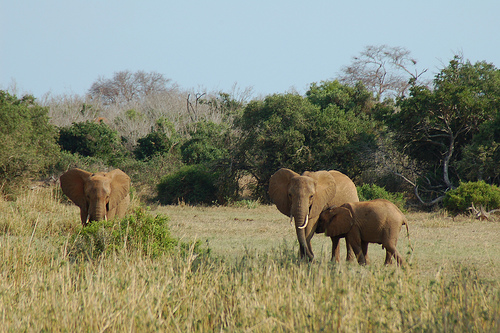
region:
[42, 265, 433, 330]
the field is brown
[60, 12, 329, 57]
the sky is dreary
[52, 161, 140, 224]
the elephant is standing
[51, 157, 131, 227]
the elephant is forward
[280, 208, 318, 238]
the elephant has tusks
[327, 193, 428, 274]
the elephant is a baby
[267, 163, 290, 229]
the elephant has a big ear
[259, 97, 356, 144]
the trees are healthy and lush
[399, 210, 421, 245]
the elephant has a small tail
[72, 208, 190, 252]
the bush is small and green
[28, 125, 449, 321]
elephants standing on flat ground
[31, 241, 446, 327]
tan grasses with spots of green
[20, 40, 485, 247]
trees of varying heights behind elephants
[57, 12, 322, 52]
clear light blue sky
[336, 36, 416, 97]
leafless tree above other trees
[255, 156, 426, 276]
adult with side to young elephant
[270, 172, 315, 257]
tusk curled in front of trunk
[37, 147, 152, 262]
elephant behind green shrub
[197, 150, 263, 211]
opening between tree and shrub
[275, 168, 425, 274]
young elephant reaching under adult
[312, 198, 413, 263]
a baby elephant nursing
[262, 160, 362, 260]
a mother elephant with her baby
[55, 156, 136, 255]
an elephant standing near a mother elephant and her baby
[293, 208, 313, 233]
a white ivory tusk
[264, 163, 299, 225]
a large elephant ear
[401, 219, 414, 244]
a baby elephant tail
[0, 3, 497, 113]
a pale blue sky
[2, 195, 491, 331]
dry savannah grass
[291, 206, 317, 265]
a long elephant trunk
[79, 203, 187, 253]
a bush in front of an elephant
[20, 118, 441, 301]
elephants outside in nature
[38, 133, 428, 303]
some elephants outside in nature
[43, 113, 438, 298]
three elephants outside in nature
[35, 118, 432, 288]
big elephants outside in nature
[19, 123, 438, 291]
strong elephants outside in nature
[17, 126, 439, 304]
group of elephants outside in nature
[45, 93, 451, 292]
mighty elephants outside in nature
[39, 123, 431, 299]
nice size elephants outside in nature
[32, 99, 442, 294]
powerful elephants outside in nature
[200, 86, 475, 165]
set of green trees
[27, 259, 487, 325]
tall brown grass in front of elephants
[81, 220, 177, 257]
a clump of tall green grass in front of an elephant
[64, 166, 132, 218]
a brown elephant standing behind grass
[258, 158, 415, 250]
a mother and baby elephant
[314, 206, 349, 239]
a baby elephant's head underneath its mother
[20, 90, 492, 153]
several green trees behind the elephants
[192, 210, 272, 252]
open flat grass land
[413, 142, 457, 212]
an oddly curved tree to the right of the elephants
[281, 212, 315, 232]
two white tusks on an elephant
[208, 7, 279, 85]
the clear blue sky